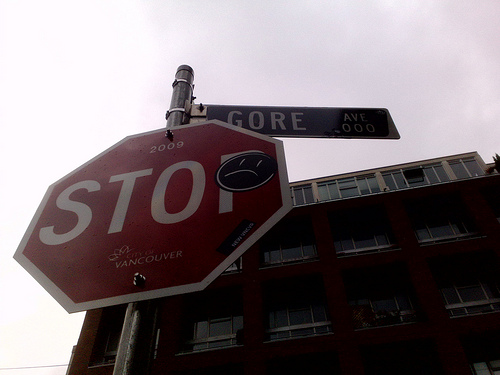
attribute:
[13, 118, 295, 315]
sign — red, white, defaced, here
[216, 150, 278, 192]
sticker — sad, black, present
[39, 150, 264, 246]
print — white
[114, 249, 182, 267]
text — white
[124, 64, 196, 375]
pole — metal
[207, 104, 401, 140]
sign — blue, white, here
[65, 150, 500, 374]
building — brown, tall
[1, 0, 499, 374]
sky — here, cloudy, overcast, grey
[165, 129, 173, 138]
screw — here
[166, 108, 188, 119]
bracket — silver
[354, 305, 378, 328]
flowers — here